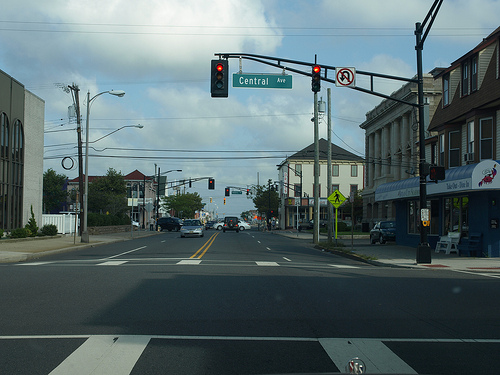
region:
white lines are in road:
[93, 243, 133, 280]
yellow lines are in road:
[194, 238, 224, 264]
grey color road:
[43, 273, 110, 305]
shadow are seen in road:
[95, 266, 210, 309]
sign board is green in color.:
[322, 186, 349, 231]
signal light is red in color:
[206, 61, 326, 76]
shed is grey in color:
[371, 177, 494, 197]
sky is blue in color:
[283, 18, 380, 53]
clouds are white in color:
[108, 3, 200, 49]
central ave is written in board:
[231, 72, 291, 89]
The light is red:
[205, 50, 236, 96]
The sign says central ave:
[228, 68, 293, 89]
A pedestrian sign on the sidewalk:
[323, 185, 348, 241]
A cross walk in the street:
[7, 250, 392, 276]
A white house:
[275, 132, 356, 218]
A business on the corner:
[435, 0, 497, 255]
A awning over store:
[365, 155, 496, 205]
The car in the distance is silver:
[175, 210, 205, 240]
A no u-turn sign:
[335, 62, 356, 88]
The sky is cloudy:
[6, 3, 297, 153]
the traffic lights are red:
[210, 58, 229, 96]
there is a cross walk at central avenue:
[14, 258, 379, 268]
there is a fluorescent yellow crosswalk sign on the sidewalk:
[327, 187, 345, 238]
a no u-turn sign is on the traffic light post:
[335, 65, 355, 85]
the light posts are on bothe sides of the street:
[80, 87, 125, 242]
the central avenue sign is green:
[232, 72, 292, 88]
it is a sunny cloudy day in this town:
[0, 0, 498, 373]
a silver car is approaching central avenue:
[179, 218, 203, 237]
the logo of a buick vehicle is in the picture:
[344, 355, 367, 373]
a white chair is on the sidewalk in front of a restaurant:
[432, 230, 460, 257]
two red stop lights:
[203, 47, 327, 109]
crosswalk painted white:
[14, 245, 407, 280]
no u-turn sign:
[333, 65, 359, 90]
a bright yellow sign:
[325, 187, 352, 241]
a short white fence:
[45, 202, 84, 233]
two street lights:
[91, 79, 146, 143]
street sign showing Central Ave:
[233, 72, 296, 89]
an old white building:
[283, 137, 363, 211]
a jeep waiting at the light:
[221, 213, 241, 233]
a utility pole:
[61, 72, 86, 241]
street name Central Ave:
[230, 67, 294, 92]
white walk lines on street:
[3, 256, 498, 368]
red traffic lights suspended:
[208, 52, 324, 102]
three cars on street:
[176, 208, 254, 238]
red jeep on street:
[219, 215, 241, 233]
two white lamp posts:
[81, 82, 148, 249]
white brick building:
[276, 132, 372, 246]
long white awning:
[370, 157, 499, 205]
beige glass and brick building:
[3, 67, 48, 237]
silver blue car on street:
[178, 215, 206, 241]